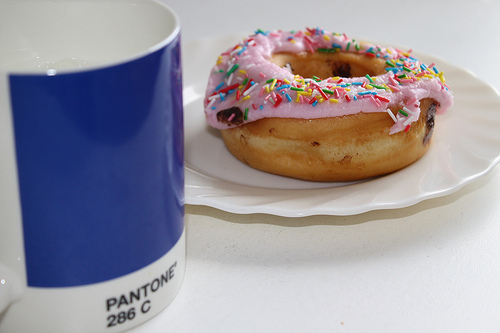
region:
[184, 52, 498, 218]
A white plate with a donut on it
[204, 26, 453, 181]
A donut with pink frosting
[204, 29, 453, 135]
Pink frosting on a donut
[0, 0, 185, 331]
A mug with writing on it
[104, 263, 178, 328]
The writing on a coffee mug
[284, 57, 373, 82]
The hole in a donut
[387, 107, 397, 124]
A white sprinkle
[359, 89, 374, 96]
A blue sprinkle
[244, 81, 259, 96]
A white sprinkle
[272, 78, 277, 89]
A yellow sprinkle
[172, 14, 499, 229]
A doughnut with sprinkles.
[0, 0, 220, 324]
A coffee mug with blue square.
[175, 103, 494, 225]
A white plate.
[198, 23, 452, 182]
A doughnut with pink icing.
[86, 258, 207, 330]
Words Pantone 286 C on cup.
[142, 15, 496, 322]
A white table.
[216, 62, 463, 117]
Colorful assortment of sprinkles.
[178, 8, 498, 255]
A single doughnut on a plate.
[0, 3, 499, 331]
A coffee mug and doughnut.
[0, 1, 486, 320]
A morning snack.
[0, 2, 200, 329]
a blue and white coffee mug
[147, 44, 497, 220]
a white plate with a design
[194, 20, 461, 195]
a colorful doughnut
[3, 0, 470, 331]
a breakfast of coffee and donuts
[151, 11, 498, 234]
a donut sitting on a plate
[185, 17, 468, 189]
a jelly-filled donut with frosting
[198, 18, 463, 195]
a donut with sprinkles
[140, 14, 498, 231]
a sweet donut on a white plate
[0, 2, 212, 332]
a mug with pantone 286 C on it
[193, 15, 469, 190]
a jelly donut with sprinkles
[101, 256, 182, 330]
black writing on the cup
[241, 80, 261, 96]
a white donut sprinkle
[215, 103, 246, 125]
a smear of chocolate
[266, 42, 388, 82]
the center of the donut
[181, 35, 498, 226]
a white saucer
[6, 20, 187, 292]
a blue square on the cup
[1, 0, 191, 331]
a white, blue, and black coffee mug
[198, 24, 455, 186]
a donut on the plate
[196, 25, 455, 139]
pink frosting on the donut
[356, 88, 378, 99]
a blue sprinkle on the donut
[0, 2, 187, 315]
A blue mug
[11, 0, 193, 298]
A white and blue mug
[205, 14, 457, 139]
Pink frosting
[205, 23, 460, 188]
Sprinkles on pink frosting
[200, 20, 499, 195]
A doughnut sitting on a plate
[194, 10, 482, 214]
A sprinkle and frosting donut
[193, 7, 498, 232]
The plate is white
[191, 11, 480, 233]
Multi-color sprinkles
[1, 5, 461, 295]
A doughnut and coffee